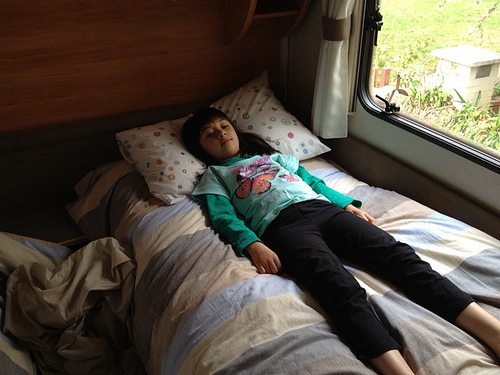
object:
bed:
[62, 84, 498, 374]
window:
[340, 0, 498, 179]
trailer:
[2, 2, 500, 375]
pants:
[261, 197, 477, 366]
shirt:
[200, 150, 364, 255]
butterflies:
[231, 155, 301, 199]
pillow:
[114, 75, 333, 209]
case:
[114, 68, 334, 208]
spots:
[119, 103, 322, 181]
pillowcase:
[116, 72, 333, 208]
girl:
[180, 106, 498, 375]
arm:
[203, 166, 266, 242]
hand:
[244, 238, 282, 278]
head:
[178, 104, 253, 163]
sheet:
[0, 235, 135, 375]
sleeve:
[293, 160, 364, 220]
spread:
[78, 151, 472, 372]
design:
[223, 148, 305, 213]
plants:
[370, 1, 500, 148]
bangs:
[189, 106, 229, 131]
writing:
[226, 155, 276, 177]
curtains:
[306, 0, 370, 144]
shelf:
[220, 2, 316, 52]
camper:
[4, 4, 499, 373]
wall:
[438, 41, 500, 119]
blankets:
[0, 232, 139, 373]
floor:
[5, 249, 137, 374]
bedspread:
[66, 138, 498, 375]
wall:
[0, 6, 316, 254]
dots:
[137, 140, 186, 183]